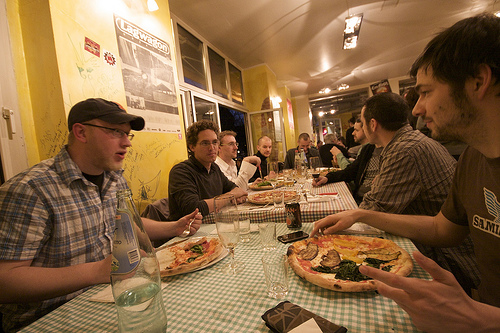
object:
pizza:
[284, 225, 419, 297]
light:
[336, 12, 364, 60]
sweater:
[167, 154, 237, 220]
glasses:
[75, 120, 133, 137]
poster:
[113, 12, 182, 136]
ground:
[404, 155, 448, 172]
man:
[2, 77, 209, 313]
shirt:
[5, 140, 149, 310]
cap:
[55, 89, 151, 134]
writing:
[31, 113, 170, 219]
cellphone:
[276, 228, 308, 245]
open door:
[218, 107, 250, 175]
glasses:
[224, 140, 242, 147]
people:
[41, 58, 498, 329]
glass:
[263, 251, 293, 300]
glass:
[257, 220, 277, 252]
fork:
[174, 210, 199, 242]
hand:
[172, 205, 205, 240]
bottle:
[103, 181, 171, 331]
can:
[282, 200, 304, 232]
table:
[9, 150, 429, 330]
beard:
[446, 83, 483, 140]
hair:
[183, 121, 219, 146]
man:
[163, 116, 250, 214]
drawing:
[134, 165, 165, 213]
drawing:
[66, 42, 112, 98]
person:
[401, 13, 491, 277]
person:
[347, 86, 438, 206]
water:
[115, 278, 167, 328]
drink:
[283, 197, 306, 231]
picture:
[103, 46, 119, 68]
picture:
[78, 30, 102, 58]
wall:
[4, 6, 193, 240]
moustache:
[424, 112, 441, 131]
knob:
[1, 107, 18, 142]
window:
[3, 97, 9, 191]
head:
[62, 101, 135, 174]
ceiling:
[167, 2, 498, 110]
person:
[356, 90, 455, 225]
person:
[212, 125, 262, 186]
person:
[281, 130, 326, 167]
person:
[329, 112, 370, 169]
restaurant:
[4, 2, 494, 325]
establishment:
[50, 65, 443, 319]